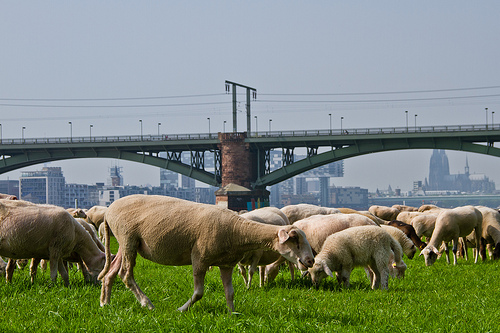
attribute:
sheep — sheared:
[98, 194, 315, 315]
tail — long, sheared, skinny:
[97, 215, 111, 281]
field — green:
[220, 265, 490, 330]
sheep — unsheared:
[309, 226, 409, 293]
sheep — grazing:
[3, 175, 499, 300]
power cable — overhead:
[1, 85, 499, 102]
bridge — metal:
[1, 79, 498, 211]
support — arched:
[291, 130, 499, 156]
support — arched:
[9, 142, 205, 174]